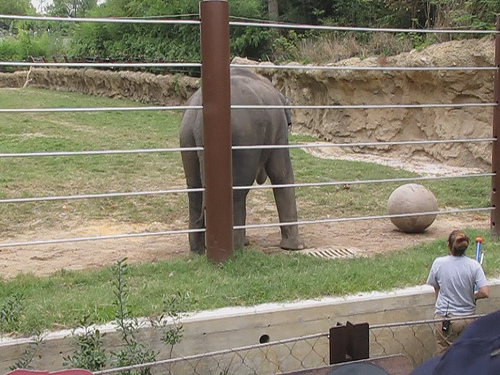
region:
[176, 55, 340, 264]
an elephant inside a cage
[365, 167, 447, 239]
he has a big ball to play with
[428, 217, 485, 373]
the lady is carrying a walkie talkie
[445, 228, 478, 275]
her hair is in a pony tail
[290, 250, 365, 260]
a drain is in the enclosure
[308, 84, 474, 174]
this appears to be a dug out embankment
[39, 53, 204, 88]
a fence runs all along the far side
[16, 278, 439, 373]
a big cement wall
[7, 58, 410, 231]
a metal fence hold the elephant inside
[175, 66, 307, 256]
rear view of an elephant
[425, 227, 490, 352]
woman in khaki pants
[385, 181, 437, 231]
a big ball in the elephant pen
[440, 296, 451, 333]
black walkie talkie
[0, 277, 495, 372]
cement wall behind the pen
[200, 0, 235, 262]
a red fence pole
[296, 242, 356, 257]
ground grate by elephant's foot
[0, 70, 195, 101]
stone like fencing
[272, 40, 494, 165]
part of the rocky structure nearer the elephant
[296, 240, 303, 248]
an elephant toe nail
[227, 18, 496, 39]
silver metal fence pole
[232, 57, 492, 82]
silver metal fence pole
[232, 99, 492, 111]
silver metal fence pole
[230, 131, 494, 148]
silver metal fence pole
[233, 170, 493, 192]
silver metal fence pole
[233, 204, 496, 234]
silver metal fence pole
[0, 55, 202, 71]
silver metal fence pole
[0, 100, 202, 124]
silver metal fence pole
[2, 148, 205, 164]
silver metal fence pole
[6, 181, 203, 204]
silver metal fence pole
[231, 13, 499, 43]
metal wires for fencing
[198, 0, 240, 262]
wooden pole to hold metal wire fence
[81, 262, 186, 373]
tall plant growing outside of pin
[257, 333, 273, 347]
hole for irrigation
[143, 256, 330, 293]
grass for naturalness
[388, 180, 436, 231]
ball for elephant to play with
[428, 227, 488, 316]
zoo keeper watching elephant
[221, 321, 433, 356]
gate keeping humans at a safe distance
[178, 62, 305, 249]
elephant standing near zoo gate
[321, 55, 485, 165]
rock wall for setting boundary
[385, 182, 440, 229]
White ball on dirt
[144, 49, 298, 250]
Elephant inside enclosure near ball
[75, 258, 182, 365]
Tall plant with green leaves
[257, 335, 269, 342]
Black hole in cement wall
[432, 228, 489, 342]
Elephant keeper near fence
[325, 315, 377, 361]
Black board on metal fence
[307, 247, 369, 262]
Grate in ground near elephant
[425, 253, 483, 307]
Gray shirt on woman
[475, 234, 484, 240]
Orange ball on blue pole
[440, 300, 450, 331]
Two way radio in pocket